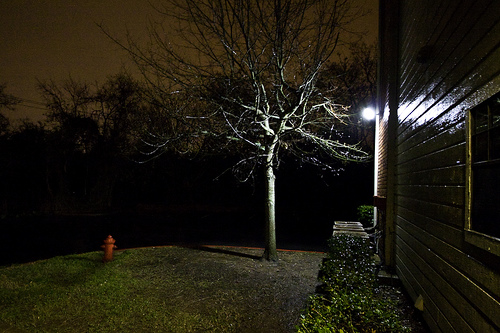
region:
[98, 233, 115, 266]
Fire hydrant in the grass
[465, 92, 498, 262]
Window on the side of the house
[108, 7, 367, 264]
Bare tree in the yard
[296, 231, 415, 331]
Flowers alongside of house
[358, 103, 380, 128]
Light shining on side of house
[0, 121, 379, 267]
Shadows in the distance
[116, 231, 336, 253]
Red line in the ground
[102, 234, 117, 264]
The fire hydrant in the grass.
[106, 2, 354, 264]
The tree to the right of the hydrant.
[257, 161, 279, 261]
The trunk of the tree.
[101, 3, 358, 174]
The branches of the tree to the right of the hydrant.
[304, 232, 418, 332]
The shrubs in front of the building.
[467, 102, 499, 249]
The window of the building.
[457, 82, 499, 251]
The frame around the window.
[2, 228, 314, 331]
The grass area in front of the shrubs.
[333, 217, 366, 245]
The air conditioner units in front of the building.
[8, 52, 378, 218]
The tree branches in the distance.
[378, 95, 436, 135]
light shining on wall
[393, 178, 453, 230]
wooden slats on side of building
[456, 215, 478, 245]
edge of window sill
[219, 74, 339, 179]
bare branches on tree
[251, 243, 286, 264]
base of bare tree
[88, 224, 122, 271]
bright red fire hydrant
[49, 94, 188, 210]
area of tall trees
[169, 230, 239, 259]
red border at edge of grass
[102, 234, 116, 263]
fire hydrant is red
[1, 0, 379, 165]
the sky is red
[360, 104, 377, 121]
outside light is on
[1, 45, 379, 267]
silhoutte tree line behind hydrant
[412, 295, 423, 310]
dryer vent on wall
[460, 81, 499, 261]
wooden windowsill on wall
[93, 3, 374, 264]
sparse brown trees with no leaves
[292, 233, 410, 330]
front row hedge by building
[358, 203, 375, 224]
green hedge behind building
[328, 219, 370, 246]
three air conditioner units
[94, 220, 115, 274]
Small red fire hydrant in the grass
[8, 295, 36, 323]
Small patch of green grass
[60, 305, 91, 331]
Small patch of green grass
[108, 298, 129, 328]
Small patch of green grass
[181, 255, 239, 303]
Small patch of green grass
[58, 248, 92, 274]
Small patch of green grass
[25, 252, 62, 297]
Small patch of green grass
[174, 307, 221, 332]
Patch of dull green grass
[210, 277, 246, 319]
Patch of dull green grass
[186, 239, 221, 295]
Patch of dull green grass